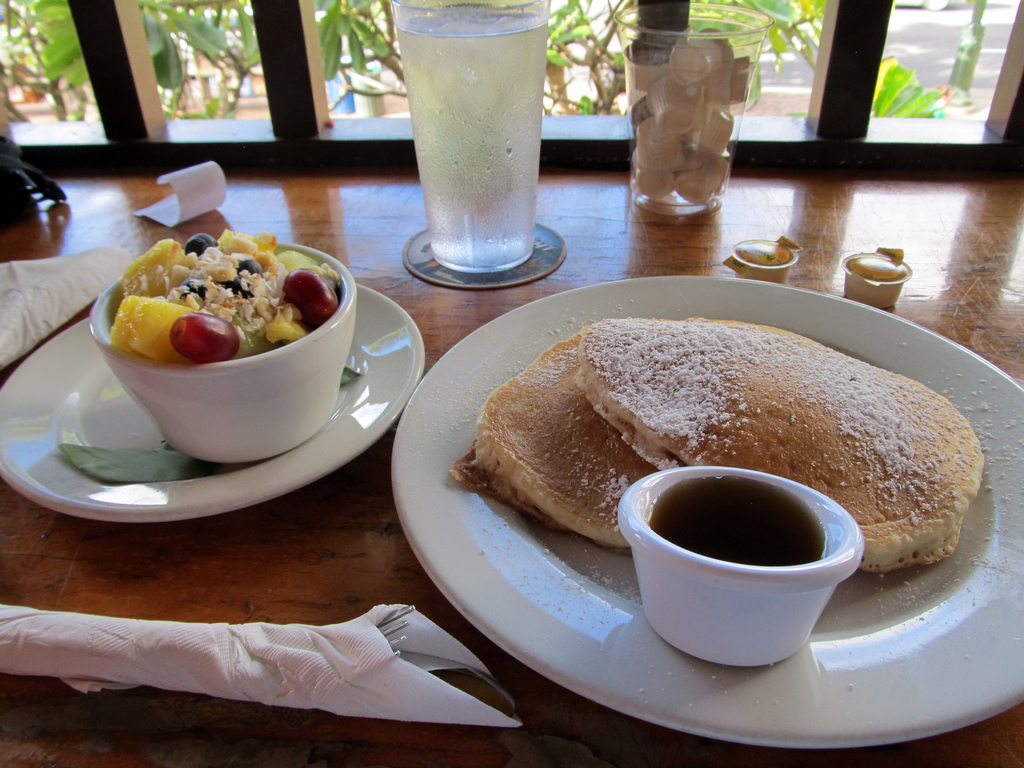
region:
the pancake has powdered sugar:
[495, 322, 970, 570]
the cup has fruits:
[107, 227, 373, 466]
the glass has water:
[401, 2, 545, 272]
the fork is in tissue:
[0, 598, 525, 741]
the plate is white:
[388, 281, 1022, 756]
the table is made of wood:
[2, 179, 1023, 765]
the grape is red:
[174, 312, 238, 367]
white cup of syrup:
[607, 444, 861, 667]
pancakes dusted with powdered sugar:
[472, 292, 978, 507]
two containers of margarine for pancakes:
[710, 204, 985, 307]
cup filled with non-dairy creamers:
[620, 10, 777, 254]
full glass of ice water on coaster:
[381, 13, 566, 283]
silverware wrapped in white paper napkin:
[4, 585, 514, 740]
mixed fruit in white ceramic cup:
[87, 221, 360, 460]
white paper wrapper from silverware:
[121, 155, 240, 236]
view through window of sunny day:
[11, 7, 1011, 135]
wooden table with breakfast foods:
[5, 164, 1015, 728]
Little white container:
[624, 467, 862, 676]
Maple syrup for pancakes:
[653, 470, 825, 563]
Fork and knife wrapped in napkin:
[2, 601, 524, 737]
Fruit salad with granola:
[93, 230, 350, 465]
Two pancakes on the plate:
[471, 319, 984, 572]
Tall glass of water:
[392, 6, 554, 279]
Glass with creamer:
[618, 6, 761, 229]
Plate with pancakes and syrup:
[392, 282, 1019, 747]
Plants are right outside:
[5, 3, 1012, 137]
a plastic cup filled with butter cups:
[614, 3, 764, 222]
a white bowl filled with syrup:
[617, 464, 864, 671]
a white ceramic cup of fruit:
[83, 226, 358, 464]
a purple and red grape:
[169, 311, 237, 365]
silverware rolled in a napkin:
[4, 597, 523, 730]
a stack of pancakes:
[467, 314, 987, 574]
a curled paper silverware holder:
[132, 159, 228, 232]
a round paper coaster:
[405, 217, 567, 290]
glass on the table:
[358, 13, 580, 296]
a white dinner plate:
[396, 240, 1022, 741]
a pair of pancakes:
[439, 300, 1005, 580]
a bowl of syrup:
[595, 443, 859, 677]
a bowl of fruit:
[82, 192, 393, 461]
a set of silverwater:
[7, 562, 584, 762]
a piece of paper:
[129, 151, 246, 232]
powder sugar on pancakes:
[543, 288, 964, 491]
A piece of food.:
[166, 313, 255, 362]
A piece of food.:
[113, 299, 209, 358]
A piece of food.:
[261, 305, 315, 347]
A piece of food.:
[277, 269, 351, 330]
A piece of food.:
[214, 248, 247, 274]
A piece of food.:
[176, 234, 218, 257]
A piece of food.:
[138, 241, 193, 271]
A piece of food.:
[152, 258, 172, 277]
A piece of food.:
[214, 282, 244, 302]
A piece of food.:
[242, 296, 268, 317]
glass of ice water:
[394, 1, 544, 274]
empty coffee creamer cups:
[726, 230, 911, 314]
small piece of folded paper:
[138, 155, 228, 225]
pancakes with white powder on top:
[451, 312, 989, 568]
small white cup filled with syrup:
[609, 462, 865, 672]